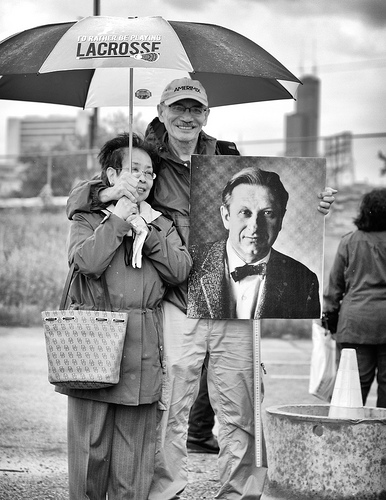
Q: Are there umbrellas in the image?
A: Yes, there is an umbrella.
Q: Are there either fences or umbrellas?
A: Yes, there is an umbrella.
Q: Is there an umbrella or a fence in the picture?
A: Yes, there is an umbrella.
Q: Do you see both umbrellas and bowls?
A: No, there is an umbrella but no bowls.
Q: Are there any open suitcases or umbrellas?
A: Yes, there is an open umbrella.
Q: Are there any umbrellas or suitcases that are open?
A: Yes, the umbrella is open.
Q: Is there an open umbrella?
A: Yes, there is an open umbrella.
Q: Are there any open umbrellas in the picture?
A: Yes, there is an open umbrella.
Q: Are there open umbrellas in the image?
A: Yes, there is an open umbrella.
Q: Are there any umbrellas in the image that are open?
A: Yes, there is an umbrella that is open.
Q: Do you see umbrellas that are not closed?
A: Yes, there is a open umbrella.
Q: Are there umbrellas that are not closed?
A: Yes, there is a open umbrella.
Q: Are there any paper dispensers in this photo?
A: No, there are no paper dispensers.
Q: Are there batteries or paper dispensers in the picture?
A: No, there are no paper dispensers or batteries.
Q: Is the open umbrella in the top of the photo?
A: Yes, the umbrella is in the top of the image.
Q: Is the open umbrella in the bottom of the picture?
A: No, the umbrella is in the top of the image.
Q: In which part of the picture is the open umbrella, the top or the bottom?
A: The umbrella is in the top of the image.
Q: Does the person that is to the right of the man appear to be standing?
A: Yes, the person is standing.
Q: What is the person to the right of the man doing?
A: The person is standing.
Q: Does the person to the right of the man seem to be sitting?
A: No, the person is standing.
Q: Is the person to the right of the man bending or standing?
A: The person is standing.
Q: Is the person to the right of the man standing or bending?
A: The person is standing.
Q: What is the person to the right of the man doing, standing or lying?
A: The person is standing.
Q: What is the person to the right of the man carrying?
A: The person is carrying a bag.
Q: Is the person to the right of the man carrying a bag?
A: Yes, the person is carrying a bag.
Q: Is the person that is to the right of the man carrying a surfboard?
A: No, the person is carrying a bag.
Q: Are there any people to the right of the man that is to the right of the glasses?
A: Yes, there is a person to the right of the man.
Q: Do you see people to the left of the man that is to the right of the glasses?
A: No, the person is to the right of the man.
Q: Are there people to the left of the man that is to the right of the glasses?
A: No, the person is to the right of the man.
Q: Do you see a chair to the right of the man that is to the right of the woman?
A: No, there is a person to the right of the man.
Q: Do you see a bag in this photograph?
A: Yes, there is a bag.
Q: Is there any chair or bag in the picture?
A: Yes, there is a bag.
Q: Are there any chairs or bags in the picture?
A: Yes, there is a bag.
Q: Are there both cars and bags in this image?
A: No, there is a bag but no cars.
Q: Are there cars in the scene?
A: No, there are no cars.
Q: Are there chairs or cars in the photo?
A: No, there are no cars or chairs.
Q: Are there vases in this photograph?
A: No, there are no vases.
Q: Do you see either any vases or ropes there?
A: No, there are no vases or ropes.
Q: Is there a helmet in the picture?
A: No, there are no helmets.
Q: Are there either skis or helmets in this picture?
A: No, there are no helmets or skis.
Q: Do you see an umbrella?
A: Yes, there is an umbrella.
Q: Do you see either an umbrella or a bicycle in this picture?
A: Yes, there is an umbrella.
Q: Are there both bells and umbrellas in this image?
A: No, there is an umbrella but no bells.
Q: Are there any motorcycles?
A: No, there are no motorcycles.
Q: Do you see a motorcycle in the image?
A: No, there are no motorcycles.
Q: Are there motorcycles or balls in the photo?
A: No, there are no motorcycles or balls.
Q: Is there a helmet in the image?
A: No, there are no helmets.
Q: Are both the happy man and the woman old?
A: Yes, both the man and the woman are old.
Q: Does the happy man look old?
A: Yes, the man is old.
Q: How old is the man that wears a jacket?
A: The man is old.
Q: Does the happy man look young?
A: No, the man is old.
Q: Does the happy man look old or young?
A: The man is old.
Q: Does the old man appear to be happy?
A: Yes, the man is happy.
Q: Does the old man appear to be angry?
A: No, the man is happy.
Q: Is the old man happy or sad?
A: The man is happy.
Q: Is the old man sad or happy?
A: The man is happy.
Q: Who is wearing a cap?
A: The man is wearing a cap.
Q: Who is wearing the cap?
A: The man is wearing a cap.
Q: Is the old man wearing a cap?
A: Yes, the man is wearing a cap.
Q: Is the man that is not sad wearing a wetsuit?
A: No, the man is wearing a cap.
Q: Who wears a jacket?
A: The man wears a jacket.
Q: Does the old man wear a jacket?
A: Yes, the man wears a jacket.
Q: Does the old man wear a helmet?
A: No, the man wears a jacket.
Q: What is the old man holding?
A: The man is holding the umbrella.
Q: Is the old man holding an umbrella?
A: Yes, the man is holding an umbrella.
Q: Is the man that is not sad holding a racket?
A: No, the man is holding an umbrella.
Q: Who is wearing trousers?
A: The man is wearing trousers.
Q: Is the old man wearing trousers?
A: Yes, the man is wearing trousers.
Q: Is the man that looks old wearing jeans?
A: No, the man is wearing trousers.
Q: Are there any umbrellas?
A: Yes, there is an umbrella.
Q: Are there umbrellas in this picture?
A: Yes, there is an umbrella.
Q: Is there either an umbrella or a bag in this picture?
A: Yes, there is an umbrella.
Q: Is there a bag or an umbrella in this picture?
A: Yes, there is an umbrella.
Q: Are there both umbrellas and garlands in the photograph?
A: No, there is an umbrella but no garlands.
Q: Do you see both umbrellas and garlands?
A: No, there is an umbrella but no garlands.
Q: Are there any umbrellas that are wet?
A: Yes, there is a wet umbrella.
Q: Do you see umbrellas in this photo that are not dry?
A: Yes, there is a wet umbrella.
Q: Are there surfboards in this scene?
A: No, there are no surfboards.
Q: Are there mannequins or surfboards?
A: No, there are no surfboards or mannequins.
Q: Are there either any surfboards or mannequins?
A: No, there are no surfboards or mannequins.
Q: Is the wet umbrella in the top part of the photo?
A: Yes, the umbrella is in the top of the image.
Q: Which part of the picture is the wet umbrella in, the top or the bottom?
A: The umbrella is in the top of the image.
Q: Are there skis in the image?
A: No, there are no skis.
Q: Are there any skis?
A: No, there are no skis.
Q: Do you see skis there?
A: No, there are no skis.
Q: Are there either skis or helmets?
A: No, there are no skis or helmets.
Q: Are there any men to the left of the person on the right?
A: Yes, there is a man to the left of the person.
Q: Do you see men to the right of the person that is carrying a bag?
A: No, the man is to the left of the person.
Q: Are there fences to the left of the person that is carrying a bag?
A: No, there is a man to the left of the person.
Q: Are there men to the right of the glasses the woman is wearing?
A: Yes, there is a man to the right of the glasses.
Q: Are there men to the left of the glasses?
A: No, the man is to the right of the glasses.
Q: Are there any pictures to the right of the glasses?
A: No, there is a man to the right of the glasses.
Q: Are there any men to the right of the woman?
A: Yes, there is a man to the right of the woman.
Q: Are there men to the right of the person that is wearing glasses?
A: Yes, there is a man to the right of the woman.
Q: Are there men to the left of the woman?
A: No, the man is to the right of the woman.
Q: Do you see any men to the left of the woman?
A: No, the man is to the right of the woman.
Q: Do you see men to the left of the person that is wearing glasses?
A: No, the man is to the right of the woman.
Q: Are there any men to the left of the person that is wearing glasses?
A: No, the man is to the right of the woman.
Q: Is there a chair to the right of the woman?
A: No, there is a man to the right of the woman.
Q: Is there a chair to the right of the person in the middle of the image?
A: No, there is a man to the right of the woman.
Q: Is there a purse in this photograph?
A: Yes, there is a purse.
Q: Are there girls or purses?
A: Yes, there is a purse.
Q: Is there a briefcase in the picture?
A: No, there are no briefcases.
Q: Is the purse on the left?
A: Yes, the purse is on the left of the image.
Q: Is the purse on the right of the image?
A: No, the purse is on the left of the image.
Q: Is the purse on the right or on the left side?
A: The purse is on the left of the image.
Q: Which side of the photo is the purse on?
A: The purse is on the left of the image.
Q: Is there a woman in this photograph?
A: Yes, there is a woman.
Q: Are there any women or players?
A: Yes, there is a woman.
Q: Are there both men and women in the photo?
A: Yes, there are both a woman and a man.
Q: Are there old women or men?
A: Yes, there is an old woman.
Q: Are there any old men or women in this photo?
A: Yes, there is an old woman.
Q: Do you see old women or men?
A: Yes, there is an old woman.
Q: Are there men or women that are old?
A: Yes, the woman is old.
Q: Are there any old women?
A: Yes, there is an old woman.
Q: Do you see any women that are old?
A: Yes, there is a woman that is old.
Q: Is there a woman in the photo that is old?
A: Yes, there is a woman that is old.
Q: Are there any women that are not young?
A: Yes, there is a old woman.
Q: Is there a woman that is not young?
A: Yes, there is a old woman.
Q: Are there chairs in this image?
A: No, there are no chairs.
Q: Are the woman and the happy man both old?
A: Yes, both the woman and the man are old.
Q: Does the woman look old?
A: Yes, the woman is old.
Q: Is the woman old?
A: Yes, the woman is old.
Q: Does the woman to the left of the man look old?
A: Yes, the woman is old.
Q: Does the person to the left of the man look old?
A: Yes, the woman is old.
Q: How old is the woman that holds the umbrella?
A: The woman is old.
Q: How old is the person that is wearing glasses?
A: The woman is old.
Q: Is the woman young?
A: No, the woman is old.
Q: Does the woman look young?
A: No, the woman is old.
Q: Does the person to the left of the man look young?
A: No, the woman is old.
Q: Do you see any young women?
A: No, there is a woman but she is old.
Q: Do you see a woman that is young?
A: No, there is a woman but she is old.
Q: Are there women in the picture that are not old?
A: No, there is a woman but she is old.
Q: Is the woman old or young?
A: The woman is old.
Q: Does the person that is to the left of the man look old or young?
A: The woman is old.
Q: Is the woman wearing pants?
A: Yes, the woman is wearing pants.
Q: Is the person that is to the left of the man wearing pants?
A: Yes, the woman is wearing pants.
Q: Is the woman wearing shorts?
A: No, the woman is wearing pants.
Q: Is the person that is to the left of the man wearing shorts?
A: No, the woman is wearing pants.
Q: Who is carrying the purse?
A: The woman is carrying the purse.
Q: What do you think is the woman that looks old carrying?
A: The woman is carrying a purse.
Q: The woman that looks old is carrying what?
A: The woman is carrying a purse.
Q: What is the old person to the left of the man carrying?
A: The woman is carrying a purse.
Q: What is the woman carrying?
A: The woman is carrying a purse.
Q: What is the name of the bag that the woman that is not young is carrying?
A: The bag is a purse.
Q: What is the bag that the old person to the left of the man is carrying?
A: The bag is a purse.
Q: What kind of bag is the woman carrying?
A: The woman is carrying a purse.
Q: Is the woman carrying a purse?
A: Yes, the woman is carrying a purse.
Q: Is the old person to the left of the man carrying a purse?
A: Yes, the woman is carrying a purse.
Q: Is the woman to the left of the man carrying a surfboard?
A: No, the woman is carrying a purse.